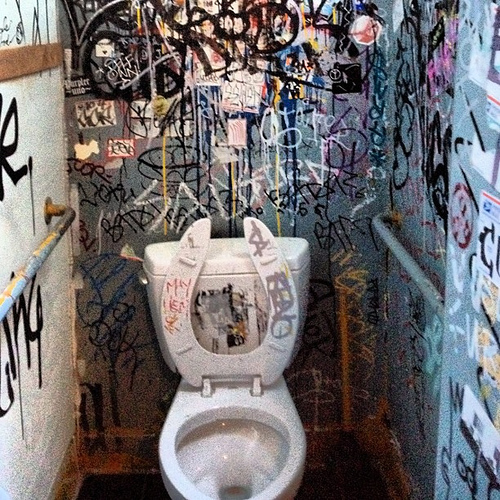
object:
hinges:
[201, 377, 213, 398]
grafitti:
[416, 111, 452, 253]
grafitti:
[2, 271, 44, 422]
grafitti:
[154, 259, 192, 348]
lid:
[160, 216, 301, 389]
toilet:
[138, 205, 320, 500]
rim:
[278, 421, 310, 481]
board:
[1, 40, 61, 82]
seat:
[161, 214, 303, 388]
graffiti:
[264, 273, 294, 341]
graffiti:
[67, 0, 380, 235]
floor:
[82, 467, 154, 499]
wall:
[78, 2, 499, 412]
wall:
[115, 77, 365, 164]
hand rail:
[373, 221, 443, 314]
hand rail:
[0, 197, 78, 324]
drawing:
[430, 382, 500, 498]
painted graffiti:
[452, 20, 488, 201]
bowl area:
[171, 405, 294, 498]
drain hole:
[214, 478, 255, 500]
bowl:
[159, 399, 306, 498]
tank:
[157, 215, 299, 388]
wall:
[2, 5, 80, 493]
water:
[222, 470, 250, 497]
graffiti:
[190, 277, 264, 352]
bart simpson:
[433, 351, 496, 498]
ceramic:
[143, 217, 311, 500]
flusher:
[135, 271, 151, 288]